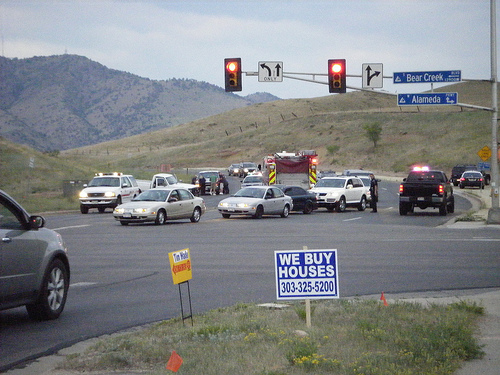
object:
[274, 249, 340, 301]
sign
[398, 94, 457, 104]
street sign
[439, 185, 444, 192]
brake lights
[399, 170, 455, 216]
pick up truck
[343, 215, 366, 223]
line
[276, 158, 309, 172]
flag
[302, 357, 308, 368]
flower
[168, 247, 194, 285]
sign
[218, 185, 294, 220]
sedan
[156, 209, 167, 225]
tire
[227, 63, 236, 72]
traffic light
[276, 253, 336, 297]
ad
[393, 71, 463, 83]
street sign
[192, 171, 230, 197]
auto accident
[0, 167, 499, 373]
street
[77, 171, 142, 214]
police car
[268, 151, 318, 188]
emergency vehicle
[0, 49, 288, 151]
hill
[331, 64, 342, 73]
traffic light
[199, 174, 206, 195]
policeman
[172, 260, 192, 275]
arrow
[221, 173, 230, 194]
emergency personnel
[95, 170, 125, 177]
lights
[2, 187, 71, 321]
silver car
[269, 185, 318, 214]
car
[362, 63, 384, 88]
traffic sign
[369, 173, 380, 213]
policeman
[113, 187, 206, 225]
car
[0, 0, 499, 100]
sky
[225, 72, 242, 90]
traffic light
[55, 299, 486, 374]
grass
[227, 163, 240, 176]
car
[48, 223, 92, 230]
line